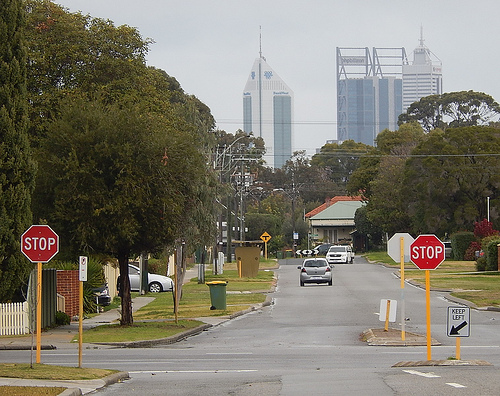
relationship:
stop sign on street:
[405, 232, 445, 275] [282, 254, 485, 362]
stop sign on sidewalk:
[15, 224, 61, 367] [12, 363, 109, 394]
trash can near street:
[212, 279, 227, 313] [282, 254, 485, 362]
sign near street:
[261, 236, 276, 267] [282, 254, 485, 362]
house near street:
[316, 196, 385, 250] [282, 254, 485, 362]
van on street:
[325, 241, 351, 262] [282, 254, 485, 362]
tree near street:
[47, 81, 206, 314] [282, 254, 485, 362]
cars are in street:
[302, 241, 355, 288] [282, 254, 485, 362]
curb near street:
[139, 327, 185, 354] [282, 254, 485, 362]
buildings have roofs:
[241, 21, 443, 168] [337, 43, 406, 75]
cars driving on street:
[302, 241, 355, 288] [282, 254, 485, 362]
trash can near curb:
[212, 279, 227, 313] [227, 300, 255, 321]